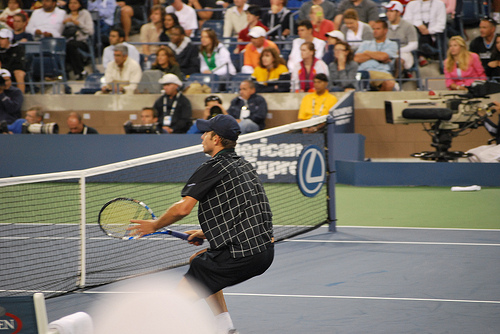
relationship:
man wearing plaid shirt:
[128, 114, 273, 333] [179, 147, 274, 258]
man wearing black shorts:
[128, 114, 276, 332] [185, 243, 278, 298]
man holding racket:
[128, 114, 273, 333] [90, 184, 223, 255]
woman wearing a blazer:
[441, 35, 487, 92] [442, 50, 484, 90]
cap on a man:
[191, 114, 241, 142] [128, 114, 273, 333]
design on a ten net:
[295, 143, 327, 195] [2, 110, 336, 315]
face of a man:
[198, 128, 213, 153] [128, 114, 276, 332]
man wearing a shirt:
[128, 114, 276, 332] [181, 150, 274, 254]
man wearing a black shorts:
[128, 114, 276, 332] [183, 243, 273, 298]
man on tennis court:
[128, 114, 273, 333] [0, 180, 498, 330]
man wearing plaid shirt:
[128, 114, 273, 333] [178, 153, 275, 256]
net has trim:
[277, 109, 327, 237] [2, 113, 329, 198]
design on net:
[295, 143, 327, 197] [0, 117, 332, 302]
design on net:
[295, 143, 327, 197] [2, 110, 336, 315]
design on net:
[295, 143, 327, 197] [0, 113, 334, 297]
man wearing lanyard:
[149, 72, 193, 144] [160, 90, 182, 128]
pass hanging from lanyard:
[160, 113, 172, 126] [160, 90, 182, 128]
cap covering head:
[185, 106, 243, 146] [197, 118, 237, 158]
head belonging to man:
[197, 118, 237, 158] [128, 114, 273, 333]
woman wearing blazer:
[436, 35, 489, 92] [442, 50, 484, 90]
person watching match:
[290, 40, 327, 99] [3, 102, 495, 328]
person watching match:
[246, 49, 292, 90] [3, 102, 495, 328]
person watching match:
[193, 26, 236, 89] [3, 102, 495, 328]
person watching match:
[98, 43, 142, 93] [3, 102, 495, 328]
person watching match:
[350, 19, 399, 89] [3, 102, 495, 328]